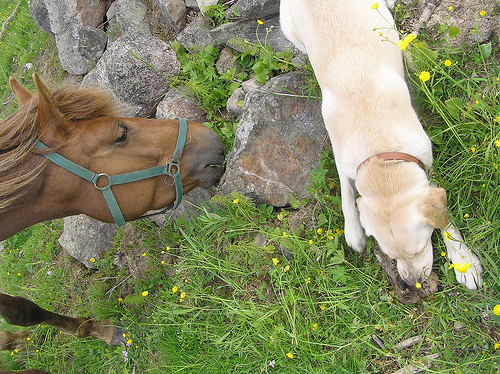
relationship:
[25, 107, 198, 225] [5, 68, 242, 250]
harness on horse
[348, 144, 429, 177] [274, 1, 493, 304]
collar on dog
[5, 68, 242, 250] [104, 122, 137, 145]
horse has eye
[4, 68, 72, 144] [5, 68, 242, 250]
ears on horse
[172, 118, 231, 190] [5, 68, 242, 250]
snout on horse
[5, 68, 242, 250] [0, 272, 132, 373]
horse has legs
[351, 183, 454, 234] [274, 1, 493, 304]
ears on dog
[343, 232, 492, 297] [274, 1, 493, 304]
paws on dog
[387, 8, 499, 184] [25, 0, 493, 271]
flowers on rocks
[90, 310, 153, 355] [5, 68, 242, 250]
hooves on horse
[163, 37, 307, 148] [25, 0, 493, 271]
grass in rocks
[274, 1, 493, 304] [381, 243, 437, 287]
dog has face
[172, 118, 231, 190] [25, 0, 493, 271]
snout in rocks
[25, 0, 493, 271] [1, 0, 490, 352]
rocks between animals